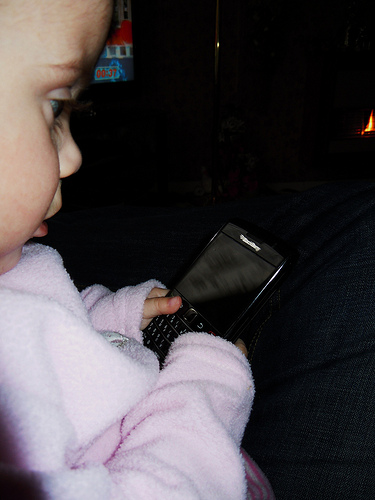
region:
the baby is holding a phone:
[27, 56, 292, 386]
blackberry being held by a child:
[129, 222, 297, 389]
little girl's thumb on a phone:
[146, 289, 185, 318]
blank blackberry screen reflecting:
[171, 229, 280, 331]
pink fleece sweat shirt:
[9, 271, 250, 494]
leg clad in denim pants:
[274, 174, 367, 479]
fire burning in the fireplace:
[335, 92, 373, 156]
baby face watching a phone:
[7, 9, 119, 287]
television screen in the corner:
[93, 9, 145, 97]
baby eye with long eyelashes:
[31, 81, 97, 142]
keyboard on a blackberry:
[154, 312, 199, 342]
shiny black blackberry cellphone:
[177, 222, 284, 365]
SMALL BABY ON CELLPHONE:
[6, 47, 346, 495]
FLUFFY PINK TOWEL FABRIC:
[0, 283, 207, 497]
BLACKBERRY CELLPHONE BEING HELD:
[148, 215, 299, 382]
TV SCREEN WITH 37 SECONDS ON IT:
[89, 56, 132, 92]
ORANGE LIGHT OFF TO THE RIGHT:
[336, 102, 372, 135]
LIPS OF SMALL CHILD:
[27, 203, 56, 232]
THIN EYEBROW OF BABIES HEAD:
[43, 44, 105, 82]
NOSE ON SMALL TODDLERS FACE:
[55, 127, 105, 191]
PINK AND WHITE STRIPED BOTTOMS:
[237, 449, 279, 496]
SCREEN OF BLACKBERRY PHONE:
[200, 233, 257, 307]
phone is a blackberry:
[141, 217, 287, 369]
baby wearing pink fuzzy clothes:
[0, 0, 275, 497]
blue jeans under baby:
[47, 182, 374, 499]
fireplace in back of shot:
[349, 103, 374, 135]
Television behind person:
[81, 1, 140, 88]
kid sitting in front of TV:
[200, 116, 267, 210]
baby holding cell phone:
[1, 0, 287, 497]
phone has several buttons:
[138, 292, 220, 372]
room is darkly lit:
[50, 0, 374, 208]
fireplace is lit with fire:
[360, 105, 372, 137]